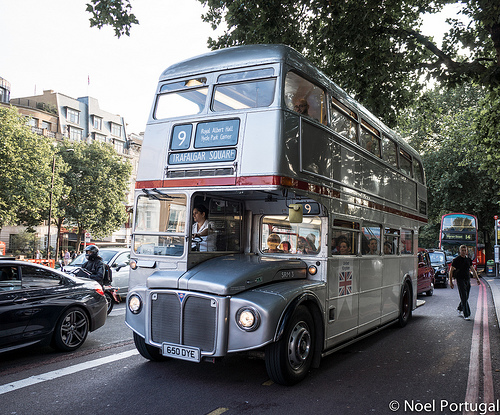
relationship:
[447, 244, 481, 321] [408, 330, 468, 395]
man walking in street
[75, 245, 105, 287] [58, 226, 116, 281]
person on motorcycle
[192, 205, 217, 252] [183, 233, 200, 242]
driver behind wheel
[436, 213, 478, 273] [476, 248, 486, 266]
bus near bus stop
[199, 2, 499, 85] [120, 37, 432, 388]
tree limb hanging over top of bus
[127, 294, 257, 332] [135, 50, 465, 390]
headlights on bus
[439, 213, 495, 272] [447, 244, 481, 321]
bus behind man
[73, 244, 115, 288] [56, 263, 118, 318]
person on motorcycle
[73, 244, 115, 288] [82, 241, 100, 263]
person wearing helmet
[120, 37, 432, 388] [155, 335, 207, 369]
bus with plate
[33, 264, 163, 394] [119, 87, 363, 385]
car driving beside a bus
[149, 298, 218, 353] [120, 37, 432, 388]
grill on bus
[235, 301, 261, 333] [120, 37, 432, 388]
headlight on bus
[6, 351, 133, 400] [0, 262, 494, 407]
line on road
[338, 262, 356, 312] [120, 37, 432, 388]
sticker on bus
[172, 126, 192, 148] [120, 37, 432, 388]
number on bus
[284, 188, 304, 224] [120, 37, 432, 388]
mirror on bus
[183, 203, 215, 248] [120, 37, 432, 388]
driver on bus